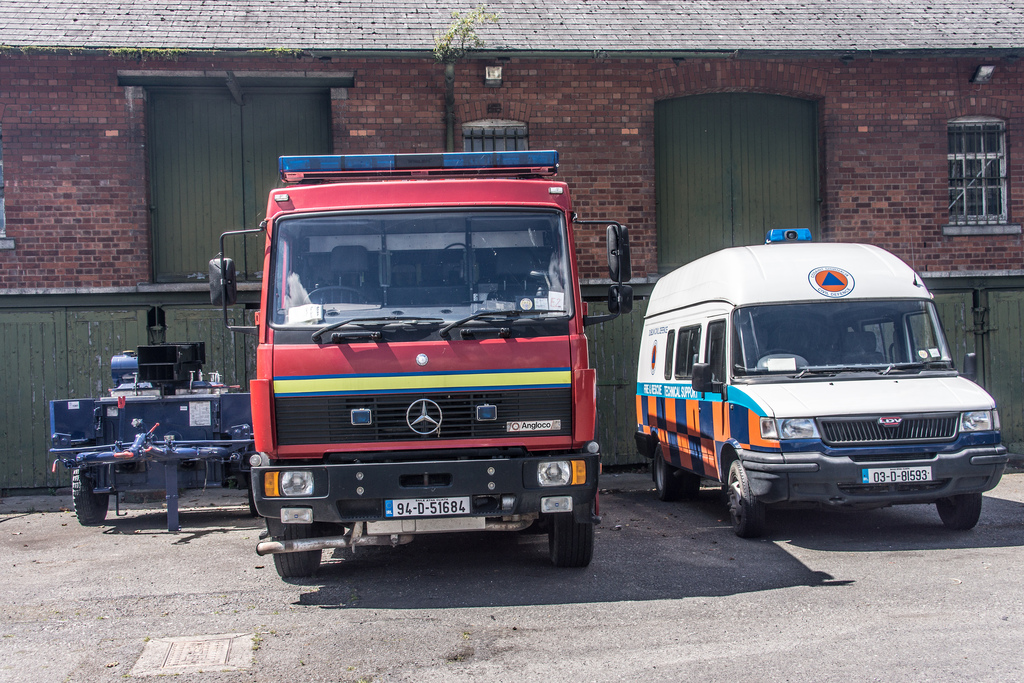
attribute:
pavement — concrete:
[276, 599, 340, 680]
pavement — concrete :
[324, 605, 382, 667]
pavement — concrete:
[377, 615, 423, 679]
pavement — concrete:
[416, 618, 475, 677]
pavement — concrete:
[469, 609, 534, 679]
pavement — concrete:
[525, 605, 576, 678]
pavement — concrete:
[573, 596, 627, 651]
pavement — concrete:
[621, 605, 661, 662]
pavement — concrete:
[675, 616, 714, 677]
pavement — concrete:
[721, 600, 778, 673]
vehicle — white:
[634, 223, 1008, 530]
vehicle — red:
[194, 138, 632, 582]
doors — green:
[646, 85, 821, 273]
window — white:
[940, 113, 1008, 225]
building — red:
[13, 16, 1013, 299]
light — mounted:
[474, 58, 506, 84]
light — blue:
[262, 134, 585, 183]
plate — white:
[382, 493, 480, 519]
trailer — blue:
[35, 300, 271, 528]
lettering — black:
[399, 502, 471, 511]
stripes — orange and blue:
[640, 377, 777, 496]